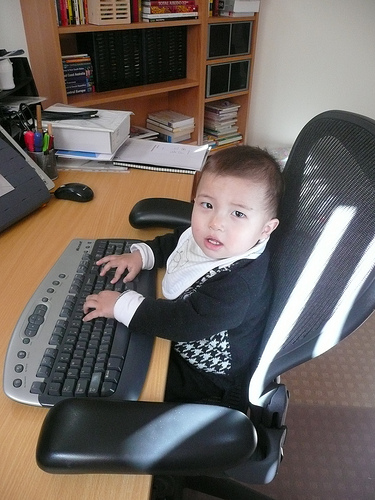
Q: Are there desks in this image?
A: Yes, there is a desk.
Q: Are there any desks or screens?
A: Yes, there is a desk.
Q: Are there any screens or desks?
A: Yes, there is a desk.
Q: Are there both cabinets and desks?
A: No, there is a desk but no cabinets.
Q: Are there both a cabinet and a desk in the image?
A: No, there is a desk but no cabinets.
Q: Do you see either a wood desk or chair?
A: Yes, there is a wood desk.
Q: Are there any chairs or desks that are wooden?
A: Yes, the desk is wooden.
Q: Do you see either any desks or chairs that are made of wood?
A: Yes, the desk is made of wood.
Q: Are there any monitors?
A: No, there are no monitors.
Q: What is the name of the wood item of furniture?
A: The piece of furniture is a desk.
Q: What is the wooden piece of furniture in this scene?
A: The piece of furniture is a desk.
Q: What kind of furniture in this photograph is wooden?
A: The furniture is a desk.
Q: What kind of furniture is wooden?
A: The furniture is a desk.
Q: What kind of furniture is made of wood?
A: The furniture is a desk.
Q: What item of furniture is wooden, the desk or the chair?
A: The desk is wooden.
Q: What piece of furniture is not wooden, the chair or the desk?
A: The chair is not wooden.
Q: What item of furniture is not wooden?
A: The piece of furniture is a chair.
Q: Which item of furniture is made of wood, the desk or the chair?
A: The desk is made of wood.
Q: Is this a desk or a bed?
A: This is a desk.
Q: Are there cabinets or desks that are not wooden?
A: No, there is a desk but it is wooden.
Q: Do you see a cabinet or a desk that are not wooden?
A: No, there is a desk but it is wooden.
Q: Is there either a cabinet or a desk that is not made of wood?
A: No, there is a desk but it is made of wood.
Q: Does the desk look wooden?
A: Yes, the desk is wooden.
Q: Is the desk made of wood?
A: Yes, the desk is made of wood.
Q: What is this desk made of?
A: The desk is made of wood.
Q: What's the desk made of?
A: The desk is made of wood.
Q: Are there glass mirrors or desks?
A: No, there is a desk but it is wooden.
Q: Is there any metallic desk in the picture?
A: No, there is a desk but it is wooden.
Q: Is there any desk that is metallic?
A: No, there is a desk but it is wooden.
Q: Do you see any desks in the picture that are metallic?
A: No, there is a desk but it is wooden.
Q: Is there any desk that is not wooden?
A: No, there is a desk but it is wooden.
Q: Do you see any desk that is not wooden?
A: No, there is a desk but it is wooden.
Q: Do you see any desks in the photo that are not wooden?
A: No, there is a desk but it is wooden.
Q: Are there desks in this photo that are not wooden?
A: No, there is a desk but it is wooden.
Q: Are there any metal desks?
A: No, there is a desk but it is made of wood.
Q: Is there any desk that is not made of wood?
A: No, there is a desk but it is made of wood.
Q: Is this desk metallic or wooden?
A: The desk is wooden.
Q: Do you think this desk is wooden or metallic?
A: The desk is wooden.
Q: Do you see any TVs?
A: No, there are no tvs.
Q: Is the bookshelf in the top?
A: Yes, the bookshelf is in the top of the image.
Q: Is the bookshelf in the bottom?
A: No, the bookshelf is in the top of the image.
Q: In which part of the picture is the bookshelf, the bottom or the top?
A: The bookshelf is in the top of the image.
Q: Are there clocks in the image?
A: No, there are no clocks.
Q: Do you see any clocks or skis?
A: No, there are no clocks or skis.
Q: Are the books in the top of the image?
A: Yes, the books are in the top of the image.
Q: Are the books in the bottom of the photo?
A: No, the books are in the top of the image.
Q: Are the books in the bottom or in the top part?
A: The books are in the top of the image.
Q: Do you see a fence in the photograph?
A: No, there are no fences.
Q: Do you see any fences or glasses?
A: No, there are no fences or glasses.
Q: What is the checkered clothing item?
A: The clothing item is a shirt.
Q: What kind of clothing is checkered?
A: The clothing is a shirt.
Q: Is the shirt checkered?
A: Yes, the shirt is checkered.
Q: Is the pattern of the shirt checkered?
A: Yes, the shirt is checkered.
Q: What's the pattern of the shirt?
A: The shirt is checkered.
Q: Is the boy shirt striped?
A: No, the shirt is checkered.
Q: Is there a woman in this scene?
A: No, there are no women.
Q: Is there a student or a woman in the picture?
A: No, there are no women or students.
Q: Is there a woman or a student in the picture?
A: No, there are no women or students.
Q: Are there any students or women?
A: No, there are no women or students.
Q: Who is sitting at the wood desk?
A: The boy is sitting at the desk.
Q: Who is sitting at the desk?
A: The boy is sitting at the desk.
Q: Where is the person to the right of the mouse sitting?
A: The boy is sitting at the desk.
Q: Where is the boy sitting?
A: The boy is sitting at the desk.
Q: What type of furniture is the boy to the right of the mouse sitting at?
A: The boy is sitting at the desk.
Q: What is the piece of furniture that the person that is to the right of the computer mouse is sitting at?
A: The piece of furniture is a desk.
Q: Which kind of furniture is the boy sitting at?
A: The boy is sitting at the desk.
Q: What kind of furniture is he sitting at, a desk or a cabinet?
A: The boy is sitting at a desk.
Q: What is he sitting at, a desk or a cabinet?
A: The boy is sitting at a desk.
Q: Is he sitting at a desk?
A: Yes, the boy is sitting at a desk.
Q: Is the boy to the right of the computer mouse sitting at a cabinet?
A: No, the boy is sitting at a desk.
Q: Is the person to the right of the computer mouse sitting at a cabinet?
A: No, the boy is sitting at a desk.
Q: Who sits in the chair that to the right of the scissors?
A: The boy sits in the chair.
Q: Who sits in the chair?
A: The boy sits in the chair.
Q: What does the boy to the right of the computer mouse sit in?
A: The boy sits in the chair.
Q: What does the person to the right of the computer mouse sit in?
A: The boy sits in the chair.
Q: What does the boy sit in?
A: The boy sits in the chair.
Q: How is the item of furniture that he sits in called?
A: The piece of furniture is a chair.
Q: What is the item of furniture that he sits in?
A: The piece of furniture is a chair.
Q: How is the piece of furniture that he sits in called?
A: The piece of furniture is a chair.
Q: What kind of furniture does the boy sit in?
A: The boy sits in the chair.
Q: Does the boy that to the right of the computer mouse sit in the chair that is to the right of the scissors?
A: Yes, the boy sits in the chair.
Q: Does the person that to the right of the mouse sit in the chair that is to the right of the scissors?
A: Yes, the boy sits in the chair.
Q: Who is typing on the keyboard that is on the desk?
A: The boy is typing on the keyboard.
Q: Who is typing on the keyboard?
A: The boy is typing on the keyboard.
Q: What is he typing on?
A: The boy is typing on the keyboard.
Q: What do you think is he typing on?
A: The boy is typing on the keyboard.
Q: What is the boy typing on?
A: The boy is typing on the keyboard.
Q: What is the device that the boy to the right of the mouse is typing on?
A: The device is a keyboard.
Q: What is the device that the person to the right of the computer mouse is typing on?
A: The device is a keyboard.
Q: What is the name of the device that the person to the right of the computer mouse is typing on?
A: The device is a keyboard.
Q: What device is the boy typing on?
A: The boy is typing on the keyboard.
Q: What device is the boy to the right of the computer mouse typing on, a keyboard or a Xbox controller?
A: The boy is typing on a keyboard.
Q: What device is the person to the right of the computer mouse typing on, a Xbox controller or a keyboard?
A: The boy is typing on a keyboard.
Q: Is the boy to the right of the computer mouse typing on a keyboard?
A: Yes, the boy is typing on a keyboard.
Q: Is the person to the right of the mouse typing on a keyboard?
A: Yes, the boy is typing on a keyboard.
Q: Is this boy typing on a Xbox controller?
A: No, the boy is typing on a keyboard.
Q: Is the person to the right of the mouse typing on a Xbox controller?
A: No, the boy is typing on a keyboard.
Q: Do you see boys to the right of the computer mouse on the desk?
A: Yes, there is a boy to the right of the computer mouse.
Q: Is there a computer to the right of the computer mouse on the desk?
A: No, there is a boy to the right of the computer mouse.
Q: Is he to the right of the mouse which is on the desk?
A: Yes, the boy is to the right of the mouse.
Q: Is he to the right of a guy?
A: No, the boy is to the right of the mouse.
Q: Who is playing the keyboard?
A: The boy is playing the keyboard.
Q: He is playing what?
A: The boy is playing the keyboard.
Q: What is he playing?
A: The boy is playing the keyboard.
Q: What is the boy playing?
A: The boy is playing the keyboard.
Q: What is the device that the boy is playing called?
A: The device is a keyboard.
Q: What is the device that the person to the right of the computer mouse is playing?
A: The device is a keyboard.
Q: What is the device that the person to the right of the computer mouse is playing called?
A: The device is a keyboard.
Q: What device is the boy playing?
A: The boy is playing the keyboard.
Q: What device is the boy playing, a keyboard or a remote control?
A: The boy is playing a keyboard.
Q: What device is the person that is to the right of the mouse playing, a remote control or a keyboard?
A: The boy is playing a keyboard.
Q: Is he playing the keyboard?
A: Yes, the boy is playing the keyboard.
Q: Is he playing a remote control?
A: No, the boy is playing the keyboard.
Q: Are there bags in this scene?
A: No, there are no bags.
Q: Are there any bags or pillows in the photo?
A: No, there are no bags or pillows.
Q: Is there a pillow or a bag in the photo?
A: No, there are no bags or pillows.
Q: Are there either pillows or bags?
A: No, there are no bags or pillows.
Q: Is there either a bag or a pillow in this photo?
A: No, there are no bags or pillows.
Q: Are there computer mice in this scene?
A: Yes, there is a computer mouse.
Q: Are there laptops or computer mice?
A: Yes, there is a computer mouse.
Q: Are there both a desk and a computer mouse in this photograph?
A: Yes, there are both a computer mouse and a desk.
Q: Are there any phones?
A: No, there are no phones.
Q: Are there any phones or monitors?
A: No, there are no phones or monitors.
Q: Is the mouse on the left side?
A: Yes, the mouse is on the left of the image.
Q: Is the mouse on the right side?
A: No, the mouse is on the left of the image.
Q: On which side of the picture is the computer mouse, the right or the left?
A: The computer mouse is on the left of the image.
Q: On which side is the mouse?
A: The mouse is on the left of the image.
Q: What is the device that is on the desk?
A: The device is a computer mouse.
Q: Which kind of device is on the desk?
A: The device is a computer mouse.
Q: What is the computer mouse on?
A: The computer mouse is on the desk.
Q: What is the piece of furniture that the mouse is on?
A: The piece of furniture is a desk.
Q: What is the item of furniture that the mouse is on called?
A: The piece of furniture is a desk.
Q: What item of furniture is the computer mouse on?
A: The mouse is on the desk.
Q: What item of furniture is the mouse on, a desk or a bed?
A: The mouse is on a desk.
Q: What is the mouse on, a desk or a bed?
A: The mouse is on a desk.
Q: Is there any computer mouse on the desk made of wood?
A: Yes, there is a computer mouse on the desk.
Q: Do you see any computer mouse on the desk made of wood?
A: Yes, there is a computer mouse on the desk.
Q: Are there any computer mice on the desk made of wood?
A: Yes, there is a computer mouse on the desk.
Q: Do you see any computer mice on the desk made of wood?
A: Yes, there is a computer mouse on the desk.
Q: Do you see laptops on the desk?
A: No, there is a computer mouse on the desk.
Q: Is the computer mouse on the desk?
A: Yes, the computer mouse is on the desk.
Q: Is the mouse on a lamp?
A: No, the mouse is on the desk.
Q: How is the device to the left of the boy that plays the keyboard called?
A: The device is a computer mouse.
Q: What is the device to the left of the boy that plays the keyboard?
A: The device is a computer mouse.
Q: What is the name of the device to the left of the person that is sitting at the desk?
A: The device is a computer mouse.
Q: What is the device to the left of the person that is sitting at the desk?
A: The device is a computer mouse.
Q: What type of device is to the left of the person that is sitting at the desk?
A: The device is a computer mouse.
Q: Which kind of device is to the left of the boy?
A: The device is a computer mouse.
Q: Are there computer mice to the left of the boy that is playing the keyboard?
A: Yes, there is a computer mouse to the left of the boy.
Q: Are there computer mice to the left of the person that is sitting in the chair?
A: Yes, there is a computer mouse to the left of the boy.